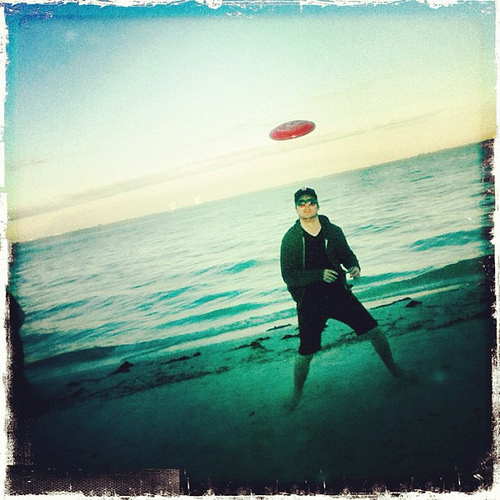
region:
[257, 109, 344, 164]
red frisbee in air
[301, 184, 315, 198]
boy has black hat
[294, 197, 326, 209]
boy has dark sunglasses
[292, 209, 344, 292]
boy has black shirt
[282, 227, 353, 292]
boy has black hoodie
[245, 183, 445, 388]
boy stands on sand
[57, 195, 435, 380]
small waves on water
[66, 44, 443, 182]
blue and orange sky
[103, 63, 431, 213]
clouds low in sky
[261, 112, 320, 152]
red frisby in air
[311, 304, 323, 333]
man wearing black shorts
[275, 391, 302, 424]
man left foot in sand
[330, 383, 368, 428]
brown sand on beach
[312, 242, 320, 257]
man wearing black shirt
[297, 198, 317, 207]
man wearing black sunglasses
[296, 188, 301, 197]
man wearing black hat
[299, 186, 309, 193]
white symbol on black hat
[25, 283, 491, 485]
Sand at the beach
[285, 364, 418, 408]
The man is not wearing shoes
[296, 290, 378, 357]
The man is wearing shorts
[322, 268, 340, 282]
The right hand of the man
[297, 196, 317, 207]
The man is wearing sunglasses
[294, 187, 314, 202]
The man is wearing a hat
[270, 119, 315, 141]
A red frisbee in the air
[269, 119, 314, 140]
The frisbee is circular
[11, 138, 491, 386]
The water behind the man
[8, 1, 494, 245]
The sky above the beach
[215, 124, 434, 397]
man playing frisbee on the beach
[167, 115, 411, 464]
man playing frisbee on the beach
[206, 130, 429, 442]
man playing frisbee on the beach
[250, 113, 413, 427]
man playing frisbee on the beach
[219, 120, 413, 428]
man playing frisbee on the beach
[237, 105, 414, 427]
man playing frisbee on the beach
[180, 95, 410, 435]
man playing frisbee on the beach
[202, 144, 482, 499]
a man on the sand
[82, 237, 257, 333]
a body of water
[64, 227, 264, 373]
a body of calm water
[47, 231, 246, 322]
a body of water that is calm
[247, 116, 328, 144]
a freesbee in the air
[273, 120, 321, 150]
a red freesbee in the air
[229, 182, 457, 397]
a man wearing sunglasses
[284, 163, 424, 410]
a man wearing a hat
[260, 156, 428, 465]
a man wearing a black hat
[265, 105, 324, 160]
frisbee in the air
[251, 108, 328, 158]
the frisbee in red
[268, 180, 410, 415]
man standing on the beach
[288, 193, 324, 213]
a pair of sunglasses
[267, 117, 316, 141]
the red plastic frisbee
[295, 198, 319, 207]
the plastic sunglasses on the face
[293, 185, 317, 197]
the black baseball hat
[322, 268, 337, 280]
the hand of the man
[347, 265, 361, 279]
the hand of the man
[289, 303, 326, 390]
the leg of the man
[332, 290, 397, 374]
the leg of the man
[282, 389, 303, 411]
the foot of the man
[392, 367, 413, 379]
the foot of the man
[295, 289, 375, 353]
the black shorts